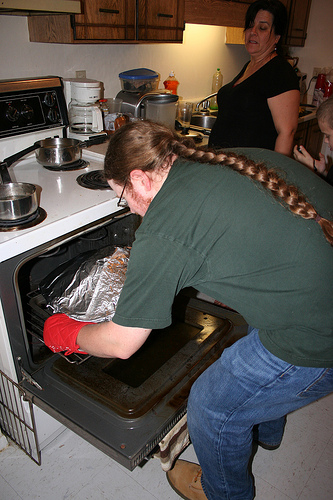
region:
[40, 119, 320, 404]
The man is taking something from the oven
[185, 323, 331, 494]
The man is wearing blue jeans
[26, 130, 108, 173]
A pot is on the stove burner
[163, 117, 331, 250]
The man has a long hair braid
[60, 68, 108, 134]
This is a coffee maker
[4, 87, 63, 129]
The stoves control knobs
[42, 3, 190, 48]
Kitchen cabinets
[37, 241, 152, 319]
Aluminum foil is covering the food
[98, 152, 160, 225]
He is wearing glasses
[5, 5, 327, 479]
A kitchen scene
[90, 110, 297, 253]
The man has red hair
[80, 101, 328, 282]
the man has a long braid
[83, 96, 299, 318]
the man is wearing glasses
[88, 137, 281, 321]
the man has a beard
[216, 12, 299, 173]
the woman is in back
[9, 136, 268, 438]
the man pulls something out of oven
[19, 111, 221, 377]
there are two saucepans on the stove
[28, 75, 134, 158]
the coffeemaker is white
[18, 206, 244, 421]
the pan is covered in foil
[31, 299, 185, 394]
the man has a red oven mit on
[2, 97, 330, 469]
man pulling food out of oven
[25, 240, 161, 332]
food wrapped in aluminum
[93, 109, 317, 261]
man's hair is braided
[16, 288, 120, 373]
oven mitts are red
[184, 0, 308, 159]
woman is watching man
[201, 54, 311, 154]
woman's shirt is black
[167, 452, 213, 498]
man's shoes are brown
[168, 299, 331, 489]
man's jeans are blue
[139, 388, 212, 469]
towel is brown and white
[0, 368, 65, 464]
oven rack on side of oven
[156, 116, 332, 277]
The man has a braid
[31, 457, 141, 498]
The floor is light colored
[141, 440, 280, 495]
The man has boots on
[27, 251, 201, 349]
The man is putting something in the oven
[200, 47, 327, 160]
The woman has a black shirt on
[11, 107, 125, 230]
The pans are on the stove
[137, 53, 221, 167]
The dish soap is by the sink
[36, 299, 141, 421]
The man has a pot holder on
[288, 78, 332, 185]
The child is in the kitchen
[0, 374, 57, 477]
The rack is out of the oven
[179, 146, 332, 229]
long brown braid running down the back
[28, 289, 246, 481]
oven door is hanging open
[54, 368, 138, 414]
brown rust on the oven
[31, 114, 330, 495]
man taking something out of the oven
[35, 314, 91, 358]
red oven mitt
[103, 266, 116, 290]
creases in the tin foil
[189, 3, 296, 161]
woman standing in the kitchen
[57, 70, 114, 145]
white coffee maker on the counter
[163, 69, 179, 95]
plastic bottle of orange dish soap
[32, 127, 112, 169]
silver pot on the stovetop